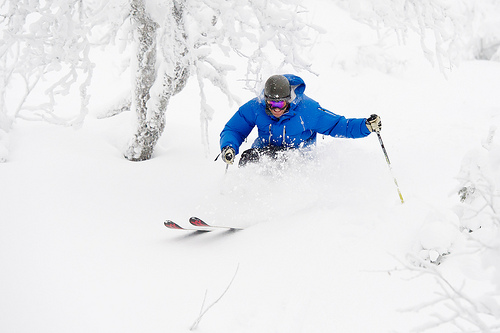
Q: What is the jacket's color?
A: Blue.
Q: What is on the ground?
A: Snow.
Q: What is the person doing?
A: Skier.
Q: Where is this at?
A: Forest.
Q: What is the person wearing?
A: Jacket.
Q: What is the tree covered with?
A: Snow.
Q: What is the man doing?
A: Skiing.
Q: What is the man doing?
A: Skiing.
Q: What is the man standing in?
A: Snow.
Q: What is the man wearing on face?
A: Goggles.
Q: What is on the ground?
A: Snow.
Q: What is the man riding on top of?
A: Skis.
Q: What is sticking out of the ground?
A: Skis.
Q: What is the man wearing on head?
A: Helmet.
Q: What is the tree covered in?
A: Snow.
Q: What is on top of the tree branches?
A: Snoww.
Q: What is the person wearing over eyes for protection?
A: Safety goggles.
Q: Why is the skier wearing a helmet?
A: Safety.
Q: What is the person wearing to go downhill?
A: Skis.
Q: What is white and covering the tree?
A: Snow.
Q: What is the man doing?
A: Skiing.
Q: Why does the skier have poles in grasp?
A: Balance.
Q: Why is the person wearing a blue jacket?
A: Warmth.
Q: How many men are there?
A: One.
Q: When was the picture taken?
A: Daytime.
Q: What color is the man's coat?
A: Blue.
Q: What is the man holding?
A: Ski poles.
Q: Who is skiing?
A: The man.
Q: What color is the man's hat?
A: Gray.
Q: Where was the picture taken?
A: On a ski slope.